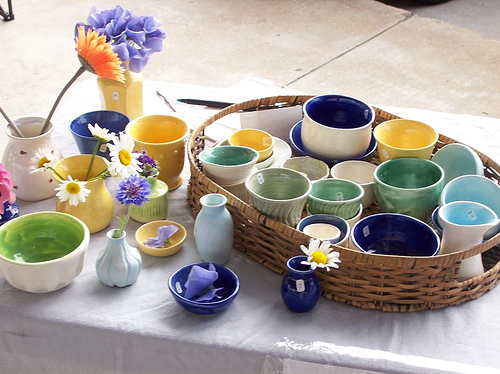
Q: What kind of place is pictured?
A: It is a sidewalk.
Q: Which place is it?
A: It is a sidewalk.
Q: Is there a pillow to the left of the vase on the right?
A: No, there is a bowl to the left of the vase.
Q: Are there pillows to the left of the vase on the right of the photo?
A: No, there is a bowl to the left of the vase.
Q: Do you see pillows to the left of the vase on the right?
A: No, there is a bowl to the left of the vase.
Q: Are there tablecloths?
A: Yes, there is a tablecloth.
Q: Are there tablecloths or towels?
A: Yes, there is a tablecloth.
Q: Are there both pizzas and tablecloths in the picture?
A: No, there is a tablecloth but no pizzas.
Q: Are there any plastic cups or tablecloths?
A: Yes, there is a plastic tablecloth.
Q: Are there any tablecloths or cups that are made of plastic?
A: Yes, the tablecloth is made of plastic.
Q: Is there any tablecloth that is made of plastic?
A: Yes, there is a tablecloth that is made of plastic.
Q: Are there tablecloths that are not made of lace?
A: Yes, there is a tablecloth that is made of plastic.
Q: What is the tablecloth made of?
A: The table cloth is made of plastic.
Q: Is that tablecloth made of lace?
A: No, the tablecloth is made of plastic.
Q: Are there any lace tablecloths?
A: No, there is a tablecloth but it is made of plastic.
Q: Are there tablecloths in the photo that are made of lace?
A: No, there is a tablecloth but it is made of plastic.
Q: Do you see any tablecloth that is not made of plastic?
A: No, there is a tablecloth but it is made of plastic.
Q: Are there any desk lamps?
A: No, there are no desk lamps.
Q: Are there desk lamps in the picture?
A: No, there are no desk lamps.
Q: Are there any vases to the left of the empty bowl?
A: No, the vase is to the right of the bowl.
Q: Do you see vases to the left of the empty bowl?
A: No, the vase is to the right of the bowl.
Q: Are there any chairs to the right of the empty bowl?
A: No, there is a vase to the right of the bowl.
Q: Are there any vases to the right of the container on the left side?
A: Yes, there is a vase to the right of the container.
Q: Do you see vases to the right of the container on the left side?
A: Yes, there is a vase to the right of the container.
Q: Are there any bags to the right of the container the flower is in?
A: No, there is a vase to the right of the container.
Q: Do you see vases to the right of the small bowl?
A: Yes, there is a vase to the right of the bowl.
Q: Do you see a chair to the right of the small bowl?
A: No, there is a vase to the right of the bowl.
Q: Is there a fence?
A: No, there are no fences.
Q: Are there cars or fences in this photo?
A: No, there are no fences or cars.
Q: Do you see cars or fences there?
A: No, there are no fences or cars.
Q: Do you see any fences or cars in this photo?
A: No, there are no fences or cars.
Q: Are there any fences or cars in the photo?
A: No, there are no fences or cars.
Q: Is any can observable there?
A: No, there are no cans.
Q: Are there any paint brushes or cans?
A: No, there are no cans or paint brushes.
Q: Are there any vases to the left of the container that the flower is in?
A: Yes, there is a vase to the left of the container.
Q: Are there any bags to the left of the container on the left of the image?
A: No, there is a vase to the left of the container.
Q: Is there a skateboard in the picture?
A: No, there are no skateboards.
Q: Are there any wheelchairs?
A: No, there are no wheelchairs.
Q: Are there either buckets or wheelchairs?
A: No, there are no wheelchairs or buckets.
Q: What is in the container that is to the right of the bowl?
A: The daisy is in the container.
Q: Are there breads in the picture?
A: No, there are no breads.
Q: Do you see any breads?
A: No, there are no breads.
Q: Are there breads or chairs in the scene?
A: No, there are no breads or chairs.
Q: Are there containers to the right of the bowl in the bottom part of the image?
A: Yes, there is a container to the right of the bowl.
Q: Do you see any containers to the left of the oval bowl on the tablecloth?
A: No, the container is to the right of the bowl.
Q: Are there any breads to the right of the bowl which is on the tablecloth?
A: No, there is a container to the right of the bowl.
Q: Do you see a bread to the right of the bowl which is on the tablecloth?
A: No, there is a container to the right of the bowl.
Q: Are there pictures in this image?
A: No, there are no pictures.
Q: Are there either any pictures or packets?
A: No, there are no pictures or packets.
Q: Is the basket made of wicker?
A: Yes, the basket is made of wicker.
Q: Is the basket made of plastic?
A: No, the basket is made of wicker.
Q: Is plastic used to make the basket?
A: No, the basket is made of wicker.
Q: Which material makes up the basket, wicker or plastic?
A: The basket is made of wicker.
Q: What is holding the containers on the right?
A: The basket is holding the containers.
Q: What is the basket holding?
A: The basket is holding the containers.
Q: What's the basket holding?
A: The basket is holding the containers.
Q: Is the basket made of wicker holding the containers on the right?
A: Yes, the basket is holding the containers.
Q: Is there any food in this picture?
A: No, there is no food.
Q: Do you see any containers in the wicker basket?
A: Yes, there are containers in the basket.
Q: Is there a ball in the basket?
A: No, there are containers in the basket.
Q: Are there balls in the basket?
A: No, there are containers in the basket.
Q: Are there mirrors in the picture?
A: No, there are no mirrors.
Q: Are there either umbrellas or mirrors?
A: No, there are no mirrors or umbrellas.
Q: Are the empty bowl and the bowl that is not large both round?
A: Yes, both the bowl and the bowl are round.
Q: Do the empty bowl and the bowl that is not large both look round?
A: Yes, both the bowl and the bowl are round.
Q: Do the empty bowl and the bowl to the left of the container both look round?
A: Yes, both the bowl and the bowl are round.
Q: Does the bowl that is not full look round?
A: Yes, the bowl is round.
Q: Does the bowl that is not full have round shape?
A: Yes, the bowl is round.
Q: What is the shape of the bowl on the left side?
A: The bowl is round.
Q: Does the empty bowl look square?
A: No, the bowl is round.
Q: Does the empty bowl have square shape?
A: No, the bowl is round.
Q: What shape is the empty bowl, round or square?
A: The bowl is round.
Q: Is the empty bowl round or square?
A: The bowl is round.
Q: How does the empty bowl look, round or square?
A: The bowl is round.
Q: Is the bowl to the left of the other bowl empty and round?
A: Yes, the bowl is empty and round.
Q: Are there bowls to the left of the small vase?
A: Yes, there is a bowl to the left of the vase.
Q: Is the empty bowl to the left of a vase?
A: Yes, the bowl is to the left of a vase.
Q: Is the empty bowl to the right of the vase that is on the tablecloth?
A: No, the bowl is to the left of the vase.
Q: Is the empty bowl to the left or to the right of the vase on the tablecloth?
A: The bowl is to the left of the vase.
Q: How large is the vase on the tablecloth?
A: The vase is small.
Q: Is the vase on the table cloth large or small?
A: The vase is small.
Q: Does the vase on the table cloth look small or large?
A: The vase is small.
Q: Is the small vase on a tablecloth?
A: Yes, the vase is on a tablecloth.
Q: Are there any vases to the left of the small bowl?
A: Yes, there is a vase to the left of the bowl.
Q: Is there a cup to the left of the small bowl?
A: No, there is a vase to the left of the bowl.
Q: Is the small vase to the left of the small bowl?
A: Yes, the vase is to the left of the bowl.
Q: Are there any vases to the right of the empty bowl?
A: Yes, there is a vase to the right of the bowl.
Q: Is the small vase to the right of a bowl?
A: Yes, the vase is to the right of a bowl.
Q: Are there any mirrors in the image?
A: No, there are no mirrors.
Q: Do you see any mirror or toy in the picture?
A: No, there are no mirrors or toys.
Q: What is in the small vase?
A: The flower is in the vase.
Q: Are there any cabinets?
A: No, there are no cabinets.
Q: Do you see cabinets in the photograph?
A: No, there are no cabinets.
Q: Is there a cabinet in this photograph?
A: No, there are no cabinets.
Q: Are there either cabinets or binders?
A: No, there are no cabinets or binders.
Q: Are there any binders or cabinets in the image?
A: No, there are no cabinets or binders.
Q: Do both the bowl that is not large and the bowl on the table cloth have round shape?
A: Yes, both the bowl and the bowl are round.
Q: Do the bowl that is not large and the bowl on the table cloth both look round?
A: Yes, both the bowl and the bowl are round.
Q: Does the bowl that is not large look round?
A: Yes, the bowl is round.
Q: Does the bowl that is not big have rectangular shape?
A: No, the bowl is round.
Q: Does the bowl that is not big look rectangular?
A: No, the bowl is round.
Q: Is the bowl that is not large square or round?
A: The bowl is round.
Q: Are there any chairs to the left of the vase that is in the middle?
A: No, there is a bowl to the left of the vase.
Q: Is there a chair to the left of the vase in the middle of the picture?
A: No, there is a bowl to the left of the vase.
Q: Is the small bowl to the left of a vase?
A: Yes, the bowl is to the left of a vase.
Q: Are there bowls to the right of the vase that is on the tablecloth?
A: Yes, there is a bowl to the right of the vase.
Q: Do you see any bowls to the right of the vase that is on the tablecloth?
A: Yes, there is a bowl to the right of the vase.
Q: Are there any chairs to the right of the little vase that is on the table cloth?
A: No, there is a bowl to the right of the vase.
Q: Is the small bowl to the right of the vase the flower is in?
A: Yes, the bowl is to the right of the vase.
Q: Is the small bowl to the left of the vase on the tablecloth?
A: No, the bowl is to the right of the vase.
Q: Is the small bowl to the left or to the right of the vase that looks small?
A: The bowl is to the right of the vase.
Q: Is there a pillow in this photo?
A: No, there are no pillows.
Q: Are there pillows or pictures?
A: No, there are no pillows or pictures.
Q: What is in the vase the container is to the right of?
A: The sunflower is in the vase.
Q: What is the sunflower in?
A: The sunflower is in the vase.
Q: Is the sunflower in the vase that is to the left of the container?
A: Yes, the sunflower is in the vase.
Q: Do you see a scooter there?
A: No, there are no scooters.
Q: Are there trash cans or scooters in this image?
A: No, there are no scooters or trash cans.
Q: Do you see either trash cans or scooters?
A: No, there are no scooters or trash cans.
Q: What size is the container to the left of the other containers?
A: The container is small.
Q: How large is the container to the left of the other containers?
A: The container is small.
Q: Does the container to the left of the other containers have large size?
A: No, the container is small.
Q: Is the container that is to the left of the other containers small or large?
A: The container is small.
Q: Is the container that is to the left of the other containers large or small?
A: The container is small.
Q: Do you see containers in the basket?
A: Yes, there is a container in the basket.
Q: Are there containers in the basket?
A: Yes, there is a container in the basket.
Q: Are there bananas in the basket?
A: No, there is a container in the basket.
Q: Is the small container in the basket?
A: Yes, the container is in the basket.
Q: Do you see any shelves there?
A: No, there are no shelves.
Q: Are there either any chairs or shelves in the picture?
A: No, there are no shelves or chairs.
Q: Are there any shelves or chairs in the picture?
A: No, there are no shelves or chairs.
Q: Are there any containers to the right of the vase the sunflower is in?
A: Yes, there is a container to the right of the vase.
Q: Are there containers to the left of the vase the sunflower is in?
A: No, the container is to the right of the vase.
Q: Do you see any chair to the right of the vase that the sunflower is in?
A: No, there is a container to the right of the vase.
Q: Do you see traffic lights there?
A: No, there are no traffic lights.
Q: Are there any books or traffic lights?
A: No, there are no traffic lights or books.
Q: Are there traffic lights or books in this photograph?
A: No, there are no traffic lights or books.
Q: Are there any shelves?
A: No, there are no shelves.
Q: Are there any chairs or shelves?
A: No, there are no shelves or chairs.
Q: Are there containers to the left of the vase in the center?
A: Yes, there is a container to the left of the vase.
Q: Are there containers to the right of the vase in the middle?
A: No, the container is to the left of the vase.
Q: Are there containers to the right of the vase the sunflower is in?
A: Yes, there is a container to the right of the vase.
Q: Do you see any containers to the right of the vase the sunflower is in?
A: Yes, there is a container to the right of the vase.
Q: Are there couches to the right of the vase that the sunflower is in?
A: No, there is a container to the right of the vase.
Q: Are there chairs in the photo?
A: No, there are no chairs.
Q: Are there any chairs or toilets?
A: No, there are no chairs or toilets.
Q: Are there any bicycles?
A: No, there are no bicycles.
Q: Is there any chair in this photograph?
A: No, there are no chairs.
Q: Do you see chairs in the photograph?
A: No, there are no chairs.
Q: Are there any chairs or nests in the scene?
A: No, there are no chairs or nests.